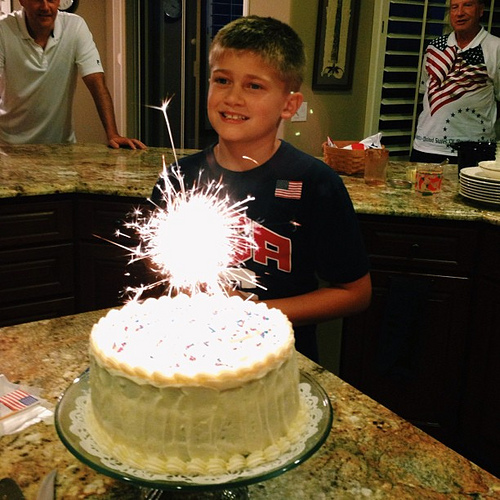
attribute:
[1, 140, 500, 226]
countertop — brown, marble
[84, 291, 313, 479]
cake — vanilla-frosted, frosted, white, iced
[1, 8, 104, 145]
polo shirt — white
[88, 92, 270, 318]
sparkler candle — fiery, on fire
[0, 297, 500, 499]
countertop — marble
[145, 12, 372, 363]
child — celebrating, smiling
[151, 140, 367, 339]
t-shirt — navy, american, blue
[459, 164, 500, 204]
plates — ivory, white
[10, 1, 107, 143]
wall — beige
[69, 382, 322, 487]
doily — white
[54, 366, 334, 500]
cake stand — glass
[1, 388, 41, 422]
american flag — small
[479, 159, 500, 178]
bowl — white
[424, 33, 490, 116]
flag graphic — red, blue, usa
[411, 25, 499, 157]
polo shirt — colorful, white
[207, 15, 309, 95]
hair — dark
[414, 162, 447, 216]
glass — clear